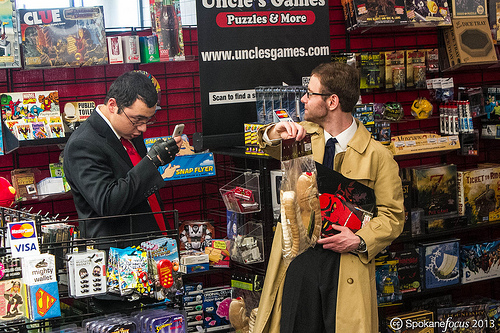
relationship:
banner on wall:
[198, 3, 335, 158] [2, 0, 499, 205]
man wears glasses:
[60, 70, 183, 253] [121, 115, 161, 130]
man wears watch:
[255, 62, 405, 333] [356, 236, 366, 253]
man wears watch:
[60, 70, 183, 253] [356, 236, 366, 253]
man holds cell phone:
[44, 62, 188, 229] [162, 119, 187, 153]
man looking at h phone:
[60, 70, 183, 253] [170, 123, 185, 140]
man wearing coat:
[255, 62, 405, 333] [245, 118, 405, 331]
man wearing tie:
[255, 62, 405, 333] [312, 132, 335, 193]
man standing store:
[60, 70, 183, 253] [3, 3, 496, 328]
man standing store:
[255, 62, 405, 333] [3, 3, 496, 328]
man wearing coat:
[255, 62, 405, 333] [251, 116, 405, 333]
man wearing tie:
[60, 70, 183, 253] [120, 135, 165, 234]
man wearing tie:
[253, 61, 405, 331] [319, 136, 339, 193]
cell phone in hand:
[166, 120, 186, 145] [260, 118, 298, 143]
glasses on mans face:
[301, 82, 341, 101] [103, 87, 157, 142]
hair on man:
[60, 64, 194, 241] [54, 60, 172, 222]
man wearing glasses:
[255, 62, 405, 333] [298, 85, 335, 101]